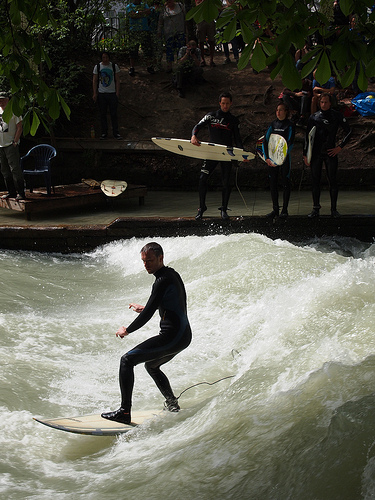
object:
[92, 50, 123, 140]
man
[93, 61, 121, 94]
shirt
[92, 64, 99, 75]
sleeve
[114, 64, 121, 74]
sleeve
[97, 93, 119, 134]
pants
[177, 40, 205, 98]
man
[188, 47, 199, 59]
camera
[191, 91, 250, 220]
man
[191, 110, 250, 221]
wetsuit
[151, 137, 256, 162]
surfboard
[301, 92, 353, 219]
man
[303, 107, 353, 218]
wetsuit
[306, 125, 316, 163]
surfboard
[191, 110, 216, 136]
sleeve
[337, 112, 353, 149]
sleeve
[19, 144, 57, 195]
chair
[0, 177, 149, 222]
platform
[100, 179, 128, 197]
surfboard